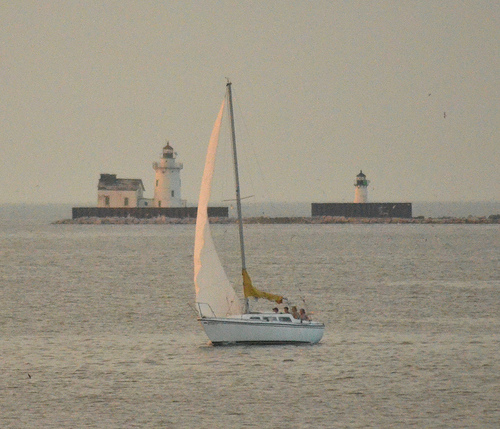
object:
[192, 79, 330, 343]
boat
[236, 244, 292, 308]
flag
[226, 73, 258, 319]
pole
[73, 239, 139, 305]
water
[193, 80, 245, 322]
sail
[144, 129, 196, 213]
light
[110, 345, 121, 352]
ripple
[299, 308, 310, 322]
people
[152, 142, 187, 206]
house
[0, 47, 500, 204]
sky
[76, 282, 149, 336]
sea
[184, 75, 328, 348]
yacht